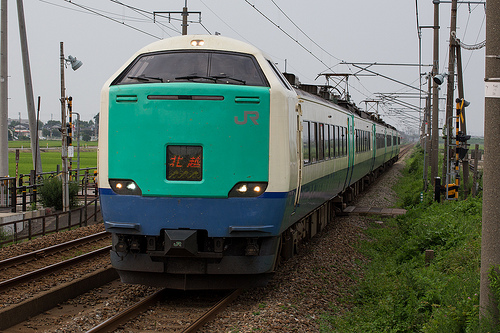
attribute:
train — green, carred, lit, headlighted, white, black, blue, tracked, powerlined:
[93, 35, 405, 276]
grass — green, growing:
[8, 132, 101, 184]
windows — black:
[300, 123, 389, 154]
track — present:
[376, 154, 424, 201]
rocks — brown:
[387, 168, 404, 186]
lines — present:
[71, 1, 367, 102]